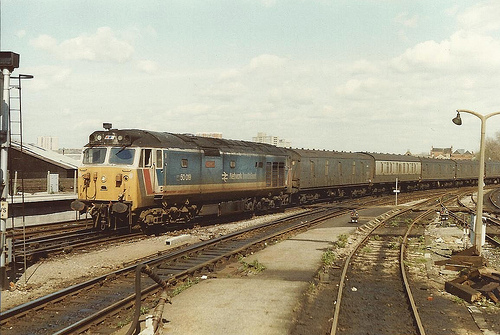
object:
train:
[69, 122, 496, 236]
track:
[18, 201, 73, 236]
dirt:
[318, 174, 344, 184]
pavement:
[228, 281, 305, 294]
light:
[452, 111, 463, 127]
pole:
[473, 118, 488, 252]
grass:
[236, 257, 267, 274]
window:
[107, 147, 133, 168]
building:
[11, 136, 78, 193]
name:
[217, 170, 258, 182]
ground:
[167, 275, 290, 335]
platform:
[7, 201, 94, 229]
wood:
[134, 262, 172, 300]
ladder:
[3, 70, 34, 152]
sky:
[0, 3, 496, 142]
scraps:
[111, 239, 131, 247]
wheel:
[139, 207, 165, 236]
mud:
[72, 235, 134, 256]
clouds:
[345, 4, 500, 102]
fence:
[60, 177, 75, 192]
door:
[170, 152, 202, 195]